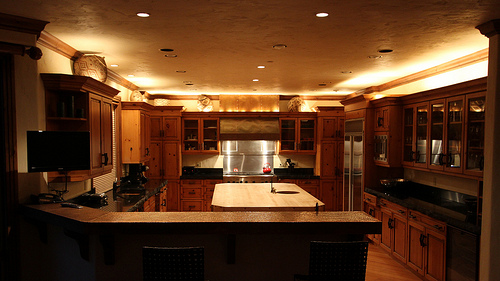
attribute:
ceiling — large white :
[160, 21, 360, 118]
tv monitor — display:
[25, 129, 93, 171]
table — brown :
[208, 176, 335, 211]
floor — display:
[358, 237, 419, 271]